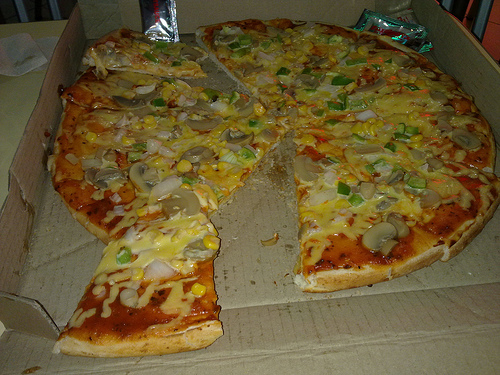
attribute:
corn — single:
[193, 283, 208, 295]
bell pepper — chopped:
[112, 244, 137, 266]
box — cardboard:
[20, 11, 340, 368]